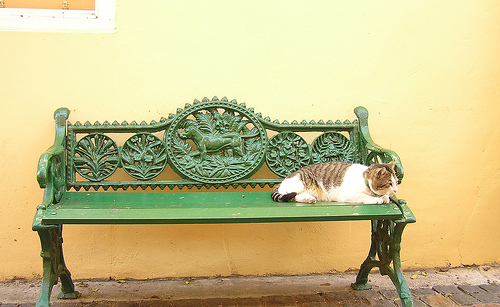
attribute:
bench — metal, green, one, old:
[31, 103, 421, 304]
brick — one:
[441, 279, 485, 306]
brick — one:
[410, 277, 440, 300]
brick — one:
[450, 293, 488, 305]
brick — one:
[360, 284, 399, 305]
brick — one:
[358, 293, 393, 305]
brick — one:
[287, 282, 337, 305]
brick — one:
[256, 281, 299, 305]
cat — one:
[284, 160, 400, 205]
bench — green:
[70, 116, 416, 286]